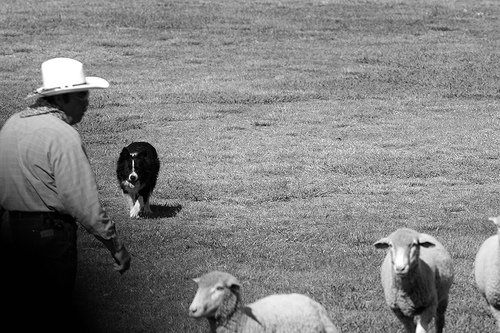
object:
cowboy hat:
[20, 55, 108, 102]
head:
[24, 56, 112, 122]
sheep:
[468, 210, 497, 314]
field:
[4, 0, 495, 331]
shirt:
[1, 101, 123, 245]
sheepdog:
[112, 141, 156, 219]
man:
[0, 57, 131, 325]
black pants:
[2, 207, 78, 321]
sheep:
[371, 227, 453, 331]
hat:
[22, 50, 136, 100]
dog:
[111, 135, 164, 220]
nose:
[192, 309, 198, 314]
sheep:
[187, 271, 337, 330]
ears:
[414, 235, 437, 247]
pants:
[0, 207, 79, 319]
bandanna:
[20, 106, 62, 118]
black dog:
[116, 143, 159, 221]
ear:
[372, 238, 389, 248]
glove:
[112, 246, 133, 273]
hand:
[104, 235, 132, 274]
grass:
[162, 5, 491, 212]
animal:
[118, 140, 158, 220]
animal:
[185, 271, 340, 330]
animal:
[371, 226, 456, 331]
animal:
[468, 213, 499, 323]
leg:
[130, 194, 144, 219]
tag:
[39, 229, 55, 239]